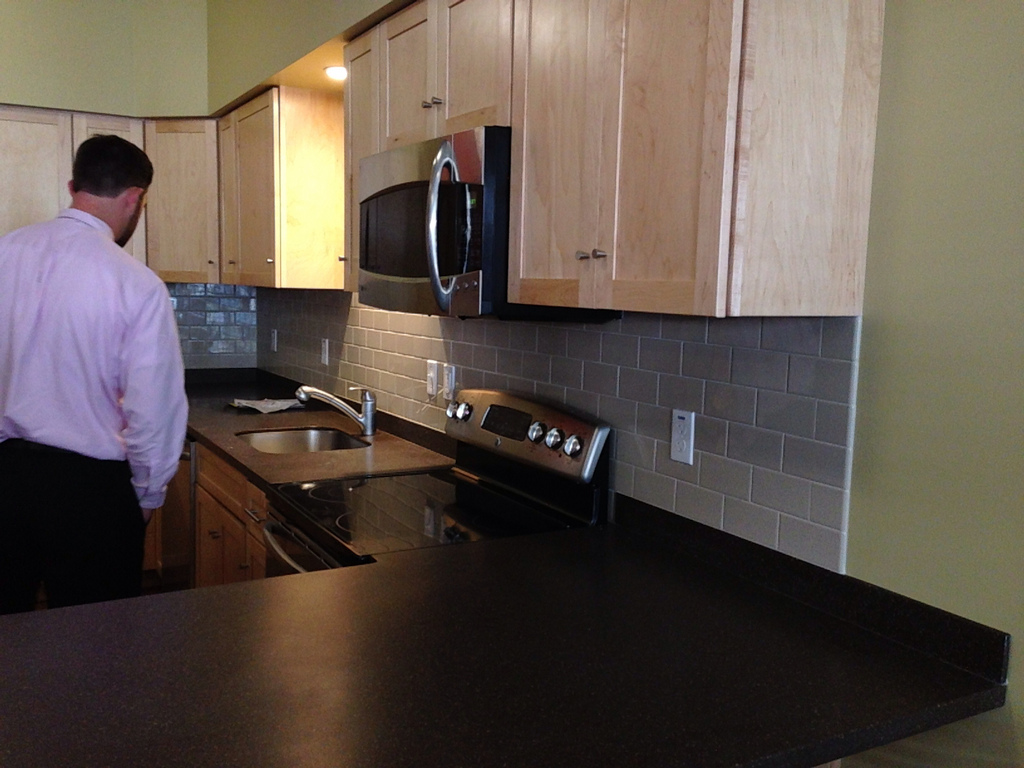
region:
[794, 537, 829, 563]
tile on the wall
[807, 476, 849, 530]
tile on the wall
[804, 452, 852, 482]
tile on the wall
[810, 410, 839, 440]
tile on the wall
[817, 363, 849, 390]
tile on the wall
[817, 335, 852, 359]
tile on the wall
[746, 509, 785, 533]
tile on the wall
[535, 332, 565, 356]
tile on the wall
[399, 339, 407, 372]
tile on the wall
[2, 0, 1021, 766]
the kitchen is clean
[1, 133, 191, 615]
the man is standing up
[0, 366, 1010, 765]
the counter top is black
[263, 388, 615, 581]
the stove is black and silver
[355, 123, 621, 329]
the microwave is silver and black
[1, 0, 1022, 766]
the cabinets in the kitchen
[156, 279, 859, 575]
the tiles are gray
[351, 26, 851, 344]
cabinets are light brown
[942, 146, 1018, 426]
wall is light green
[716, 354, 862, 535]
grey brick backsplash in kitchen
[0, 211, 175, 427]
man has white shirt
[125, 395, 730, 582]
black and silver range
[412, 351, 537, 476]
white switches on wall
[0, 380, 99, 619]
man has black pants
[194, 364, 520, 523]
a sink built into a countertop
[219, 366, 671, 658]
a black and silver stove in a kitchen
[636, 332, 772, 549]
an outlet in a wall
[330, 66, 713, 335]
a silver and black microwave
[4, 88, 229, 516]
a man with short hair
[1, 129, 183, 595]
man in a pink shirt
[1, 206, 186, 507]
pink shirt on the man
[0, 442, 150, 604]
black pants on the man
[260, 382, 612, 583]
black and silver oven in the kitchen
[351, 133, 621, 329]
black and silver microwave in the kitchen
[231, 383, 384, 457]
sink in the kitchen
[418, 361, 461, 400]
light switches over the sink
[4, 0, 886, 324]
wooden cabinets in the kitchen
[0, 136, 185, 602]
man standing in the kitchen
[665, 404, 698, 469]
white electrical outlet in the kitchen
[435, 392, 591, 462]
the knobs are silver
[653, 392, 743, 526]
the outlet is on the wall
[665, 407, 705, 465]
a white wall outlet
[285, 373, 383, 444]
a gray kitchen sink faucet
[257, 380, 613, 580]
a black and gray oven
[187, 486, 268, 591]
a brown cabinet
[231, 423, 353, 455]
a small kitchen sink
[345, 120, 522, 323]
an over the range microwave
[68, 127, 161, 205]
short cut hair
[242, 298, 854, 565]
a gray tile backsplash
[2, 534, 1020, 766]
a black counter top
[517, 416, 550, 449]
silver knob on stove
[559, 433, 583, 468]
silver knob on stove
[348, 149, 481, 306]
a silver microwave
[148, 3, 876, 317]
wooden cabinets in the kitchen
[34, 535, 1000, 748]
a black counter top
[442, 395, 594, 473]
knobs on the oven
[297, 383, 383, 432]
the faucet on the sink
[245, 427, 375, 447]
the sink on the counter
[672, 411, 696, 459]
a white electric outlet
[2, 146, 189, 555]
a man in a pink shirt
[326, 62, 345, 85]
a light in the ceiling